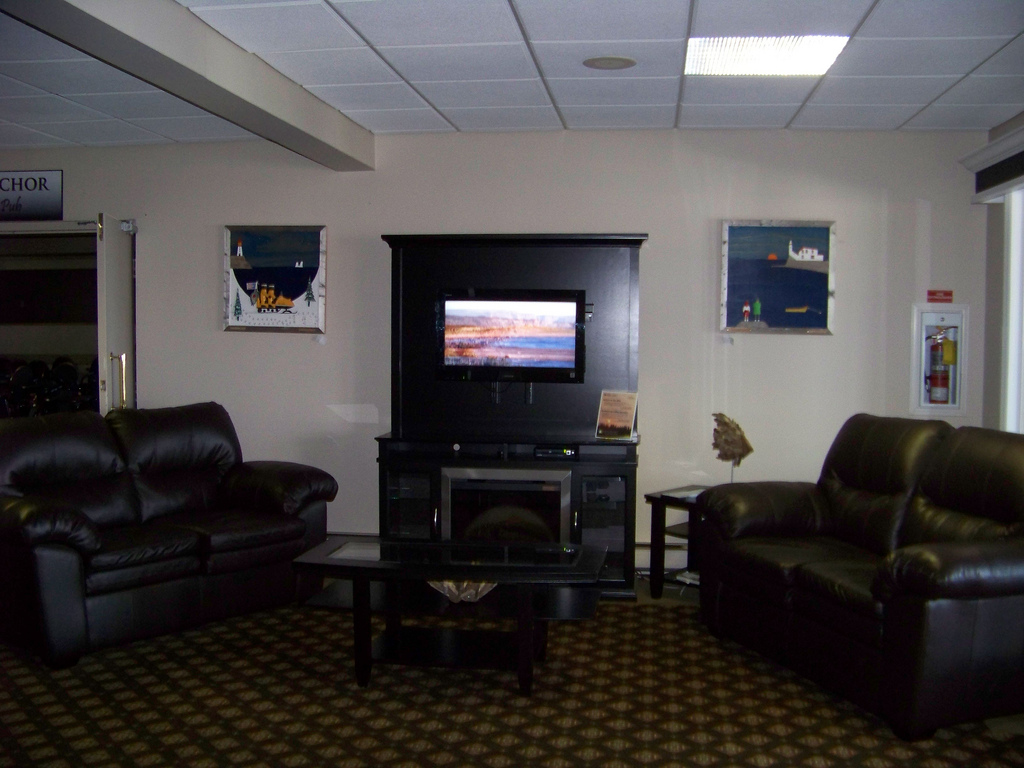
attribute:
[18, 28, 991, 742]
room — living 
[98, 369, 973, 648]
couches — two leather 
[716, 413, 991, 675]
couch — dark colored leather 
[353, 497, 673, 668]
table —  dark colored wooden coffee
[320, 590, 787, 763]
carpet — brown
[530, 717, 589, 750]
design — yellow diamond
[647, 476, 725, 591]
furniture — black 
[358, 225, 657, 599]
furniture — black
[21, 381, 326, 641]
furniture — black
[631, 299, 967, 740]
couch — brown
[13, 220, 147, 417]
door — open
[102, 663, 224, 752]
diamond — brown, yellow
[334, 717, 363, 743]
design — brown, yellow, diamond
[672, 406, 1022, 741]
couch — leather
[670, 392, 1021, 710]
furniture — black 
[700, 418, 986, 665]
furniture — black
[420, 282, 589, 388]
tv — on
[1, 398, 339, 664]
couch — black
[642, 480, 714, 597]
end table — black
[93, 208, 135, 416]
door — white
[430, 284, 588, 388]
television — on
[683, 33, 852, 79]
ceiling light — on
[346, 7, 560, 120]
tiles — white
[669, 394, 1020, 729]
sofa — leather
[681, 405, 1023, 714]
sofa — brown